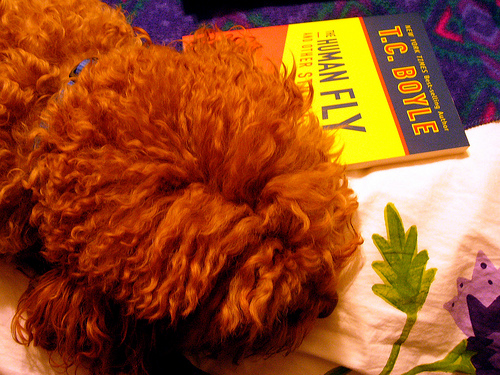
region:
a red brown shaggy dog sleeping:
[0, 0, 362, 373]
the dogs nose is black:
[316, 292, 338, 319]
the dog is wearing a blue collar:
[20, 55, 98, 150]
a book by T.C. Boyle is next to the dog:
[182, 13, 467, 166]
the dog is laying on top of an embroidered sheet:
[372, 202, 437, 374]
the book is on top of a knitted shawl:
[110, 0, 499, 128]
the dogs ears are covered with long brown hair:
[10, 266, 117, 372]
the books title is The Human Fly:
[182, 11, 469, 171]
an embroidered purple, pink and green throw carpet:
[120, 0, 499, 128]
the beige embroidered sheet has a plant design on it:
[295, 120, 497, 374]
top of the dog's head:
[19, 36, 365, 358]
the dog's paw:
[10, 272, 120, 371]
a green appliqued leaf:
[371, 204, 438, 372]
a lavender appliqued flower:
[402, 251, 499, 373]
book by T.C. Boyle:
[180, 11, 473, 171]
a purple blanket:
[137, 5, 498, 125]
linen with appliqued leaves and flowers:
[327, 120, 499, 374]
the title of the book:
[314, 27, 366, 132]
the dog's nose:
[308, 287, 340, 321]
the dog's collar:
[35, 56, 92, 139]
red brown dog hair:
[64, 107, 292, 287]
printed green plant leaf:
[365, 200, 424, 362]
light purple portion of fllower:
[448, 234, 497, 314]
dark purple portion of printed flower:
[472, 303, 496, 344]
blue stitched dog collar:
[74, 49, 105, 94]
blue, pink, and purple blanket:
[426, 21, 498, 92]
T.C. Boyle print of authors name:
[388, 24, 443, 153]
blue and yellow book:
[220, 11, 481, 165]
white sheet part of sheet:
[399, 179, 498, 222]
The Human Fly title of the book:
[303, 15, 384, 145]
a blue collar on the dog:
[27, 53, 105, 160]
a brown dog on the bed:
[0, 0, 370, 372]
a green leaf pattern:
[367, 199, 440, 374]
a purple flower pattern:
[441, 247, 498, 340]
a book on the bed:
[177, 9, 472, 176]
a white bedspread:
[0, 118, 498, 373]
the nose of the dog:
[315, 285, 340, 322]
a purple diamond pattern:
[457, 0, 499, 52]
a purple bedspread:
[96, 0, 498, 179]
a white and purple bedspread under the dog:
[0, 1, 499, 373]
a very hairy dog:
[72, 73, 342, 365]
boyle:
[385, 60, 435, 150]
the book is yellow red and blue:
[351, 104, 496, 179]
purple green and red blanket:
[457, 66, 498, 122]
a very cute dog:
[34, 113, 315, 363]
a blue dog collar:
[32, 63, 144, 132]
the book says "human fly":
[313, 35, 364, 141]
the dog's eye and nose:
[276, 278, 362, 361]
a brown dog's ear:
[13, 271, 78, 348]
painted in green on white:
[364, 209, 415, 369]